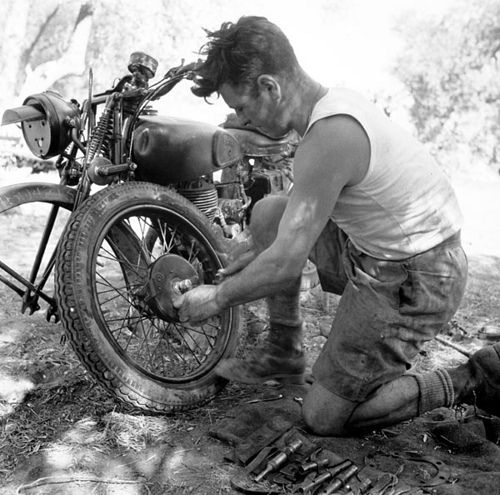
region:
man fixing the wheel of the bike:
[15, 10, 497, 457]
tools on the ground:
[227, 430, 351, 491]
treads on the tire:
[55, 281, 90, 323]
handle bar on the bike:
[161, 56, 205, 92]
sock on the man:
[415, 372, 453, 407]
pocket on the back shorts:
[406, 263, 454, 313]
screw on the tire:
[169, 274, 194, 291]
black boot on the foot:
[212, 315, 305, 389]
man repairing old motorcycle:
[0, 15, 498, 437]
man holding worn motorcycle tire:
[53, 180, 239, 412]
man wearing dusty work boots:
[212, 319, 499, 418]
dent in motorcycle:
[133, 129, 152, 156]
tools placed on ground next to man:
[252, 440, 451, 494]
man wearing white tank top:
[300, 85, 462, 262]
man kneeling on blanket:
[208, 335, 498, 494]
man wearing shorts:
[313, 218, 470, 405]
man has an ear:
[257, 74, 282, 104]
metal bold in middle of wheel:
[174, 278, 191, 293]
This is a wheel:
[12, 145, 283, 410]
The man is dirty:
[195, 91, 470, 374]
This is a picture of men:
[158, 81, 458, 321]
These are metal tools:
[220, 386, 322, 479]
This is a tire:
[53, 298, 134, 378]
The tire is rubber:
[31, 249, 201, 415]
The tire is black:
[47, 314, 125, 392]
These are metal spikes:
[118, 256, 168, 370]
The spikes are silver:
[88, 257, 158, 393]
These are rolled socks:
[406, 336, 459, 434]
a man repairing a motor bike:
[56, 25, 380, 398]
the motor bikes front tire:
[52, 180, 252, 405]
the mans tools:
[227, 419, 410, 493]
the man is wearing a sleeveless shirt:
[274, 88, 471, 298]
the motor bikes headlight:
[2, 81, 80, 156]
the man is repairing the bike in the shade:
[16, 264, 496, 483]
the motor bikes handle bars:
[82, 54, 209, 108]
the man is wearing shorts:
[304, 197, 459, 419]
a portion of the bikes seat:
[230, 118, 297, 161]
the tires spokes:
[94, 241, 149, 350]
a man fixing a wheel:
[30, 8, 497, 451]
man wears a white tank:
[148, 7, 497, 453]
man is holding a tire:
[48, 7, 472, 434]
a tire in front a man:
[50, 23, 497, 445]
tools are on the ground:
[207, 402, 386, 494]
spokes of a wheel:
[99, 208, 224, 367]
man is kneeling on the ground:
[147, 17, 499, 449]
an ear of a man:
[248, 66, 292, 102]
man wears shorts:
[138, 19, 495, 451]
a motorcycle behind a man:
[13, 8, 498, 450]